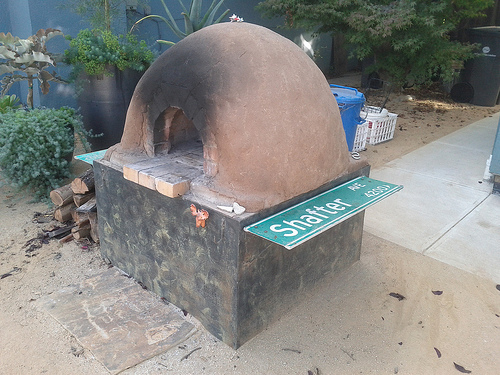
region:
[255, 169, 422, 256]
a sign that says shafter ave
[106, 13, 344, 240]
a clay pizza oven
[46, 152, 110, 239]
a stack of fire wood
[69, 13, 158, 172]
a plastic container with plants in it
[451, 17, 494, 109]
a plastic garbage can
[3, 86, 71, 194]
a potted plant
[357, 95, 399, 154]
a white plastic bin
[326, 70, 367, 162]
a blue plastic trash can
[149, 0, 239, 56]
an aloe vera plant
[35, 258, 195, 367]
a stone placed into the ground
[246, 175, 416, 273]
a street sign on the side of the oven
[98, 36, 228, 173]
black residue on the front of the oven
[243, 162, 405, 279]
the sign is green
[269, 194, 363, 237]
the letters are white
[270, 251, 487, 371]
sand is on the ground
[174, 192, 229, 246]
a sticker on the oven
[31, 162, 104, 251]
logs on the left bottom of the oven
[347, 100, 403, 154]
crates behind the oven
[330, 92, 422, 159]
the crates are white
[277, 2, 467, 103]
a tree behind the oven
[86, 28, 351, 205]
outdoor oven for baking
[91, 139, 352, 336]
stand for outdoor oven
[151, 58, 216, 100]
browned area of oven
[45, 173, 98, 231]
wood for the heat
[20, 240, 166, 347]
sand and gravel on ground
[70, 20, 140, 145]
pot with plant in it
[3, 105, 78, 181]
plant in pot on ground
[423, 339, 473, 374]
leaves on the ground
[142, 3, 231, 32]
plant behind outdoor oven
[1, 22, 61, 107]
plant behind other plants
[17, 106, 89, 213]
a plant with leaves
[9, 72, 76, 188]
a plant with green leaves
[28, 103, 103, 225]
leaves on a plant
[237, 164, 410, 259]
a sign on a structure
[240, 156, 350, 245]
a street sign on a structure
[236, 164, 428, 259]
a green and white sign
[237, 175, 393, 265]
a green and white street sign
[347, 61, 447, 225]
white baskets on the ground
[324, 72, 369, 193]
blue bucket on the ground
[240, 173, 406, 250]
a Shafter Ave street sign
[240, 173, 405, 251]
a street sign on the side of an outdoor fireplace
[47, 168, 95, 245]
firewood to use in the fireplace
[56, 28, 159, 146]
a plant in a tall pot beside the fireplace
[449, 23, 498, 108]
a trashcan on wheels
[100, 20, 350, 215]
a brick outdoor fireplace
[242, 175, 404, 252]
a green and white street sign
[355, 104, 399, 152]
three white baskets on the ground